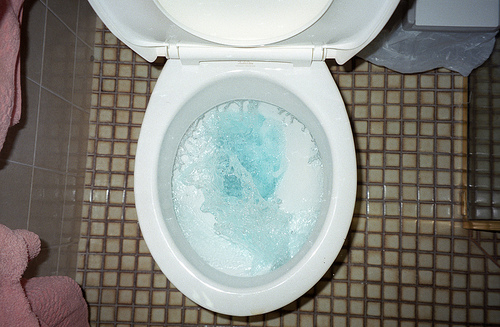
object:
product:
[173, 104, 299, 269]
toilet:
[88, 0, 407, 317]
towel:
[0, 1, 23, 151]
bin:
[405, 1, 500, 31]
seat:
[88, 0, 404, 67]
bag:
[358, 14, 499, 77]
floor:
[71, 9, 499, 326]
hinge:
[167, 46, 324, 66]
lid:
[152, 0, 331, 46]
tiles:
[75, 14, 500, 326]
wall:
[1, 2, 98, 280]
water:
[173, 98, 329, 281]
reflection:
[25, 0, 95, 284]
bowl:
[133, 60, 358, 319]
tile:
[41, 6, 75, 107]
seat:
[135, 65, 358, 316]